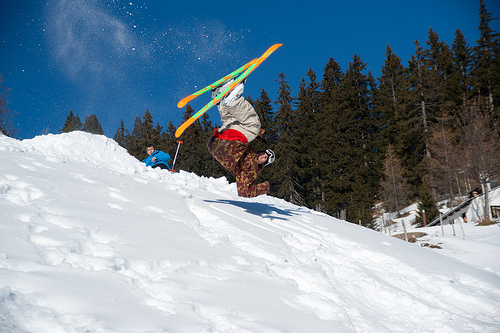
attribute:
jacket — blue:
[141, 150, 173, 168]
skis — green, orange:
[169, 45, 274, 127]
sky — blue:
[0, 0, 499, 170]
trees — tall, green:
[61, 3, 499, 239]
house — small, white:
[388, 167, 468, 234]